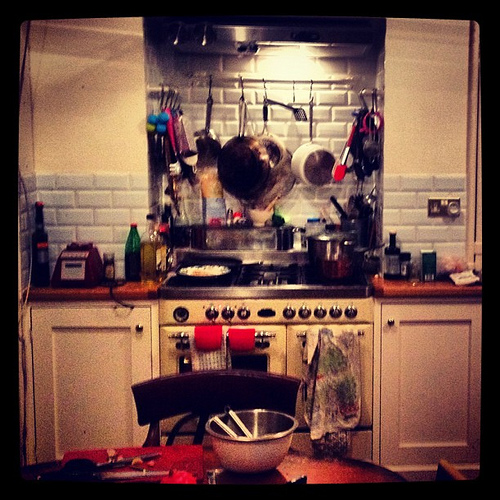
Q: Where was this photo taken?
A: In a kitchen.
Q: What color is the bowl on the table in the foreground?
A: Silver.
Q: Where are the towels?
A: Hanging over the oven handles.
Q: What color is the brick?
A: White.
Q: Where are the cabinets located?
A: On each side of the stove.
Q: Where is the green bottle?
A: To the left of the stove.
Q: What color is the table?
A: Red.